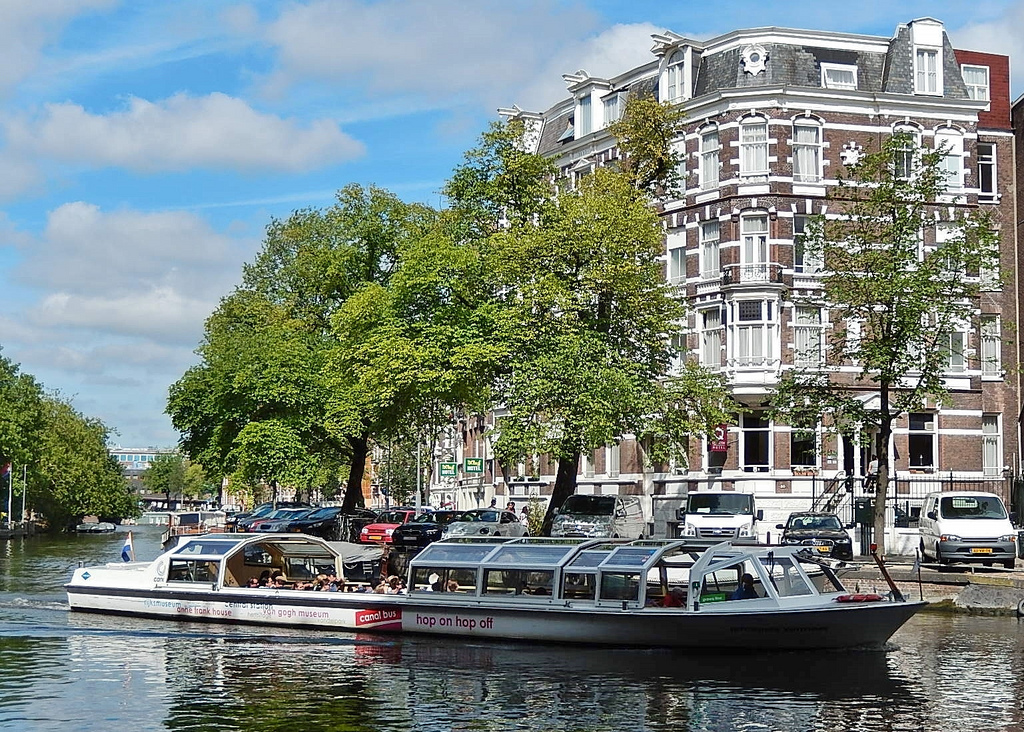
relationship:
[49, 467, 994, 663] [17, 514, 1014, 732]
boat in water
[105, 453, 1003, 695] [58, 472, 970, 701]
people on boat